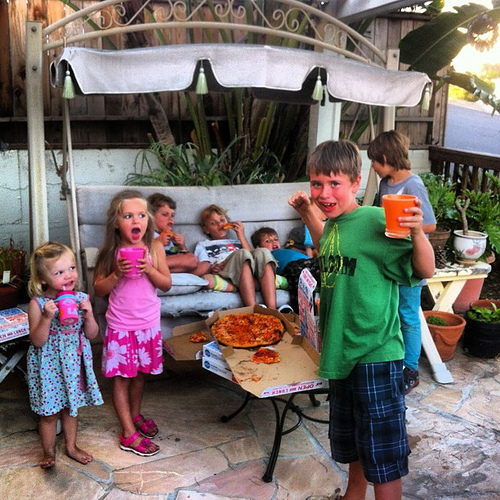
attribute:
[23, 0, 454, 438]
metal bench — tan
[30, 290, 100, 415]
dress — blue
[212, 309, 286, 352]
pizza — pepperoni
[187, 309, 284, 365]
pizza — red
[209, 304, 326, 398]
box — pizza box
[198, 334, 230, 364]
box — pizza box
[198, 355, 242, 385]
box — pizza box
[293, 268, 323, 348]
box — pizza box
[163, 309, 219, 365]
box — pizza box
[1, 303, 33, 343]
box — pizza box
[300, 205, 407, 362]
shirt — green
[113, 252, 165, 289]
cup — pink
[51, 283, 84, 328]
cup — pink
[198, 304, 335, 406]
pizza — complete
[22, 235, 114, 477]
girl — little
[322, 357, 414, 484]
shorts — plaid, blue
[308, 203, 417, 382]
tee shirt — green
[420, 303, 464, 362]
flower pot — dirty